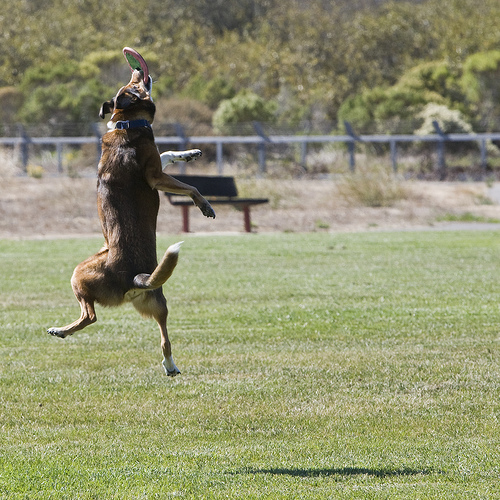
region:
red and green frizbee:
[108, 45, 166, 94]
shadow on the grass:
[193, 430, 449, 494]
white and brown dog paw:
[147, 340, 195, 392]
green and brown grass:
[251, 281, 426, 458]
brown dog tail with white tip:
[108, 232, 198, 300]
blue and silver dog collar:
[61, 106, 172, 147]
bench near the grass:
[162, 165, 272, 250]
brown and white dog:
[50, 69, 187, 416]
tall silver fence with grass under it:
[234, 113, 490, 185]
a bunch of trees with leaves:
[182, 22, 464, 119]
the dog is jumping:
[89, 37, 255, 259]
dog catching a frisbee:
[42, 26, 225, 386]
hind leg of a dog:
[28, 258, 129, 357]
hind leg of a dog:
[141, 288, 185, 395]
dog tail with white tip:
[131, 233, 191, 305]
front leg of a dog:
[118, 153, 233, 220]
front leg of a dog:
[141, 140, 211, 182]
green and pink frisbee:
[112, 34, 160, 92]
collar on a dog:
[102, 111, 159, 143]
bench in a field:
[145, 163, 261, 241]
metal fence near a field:
[0, 107, 495, 194]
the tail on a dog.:
[127, 235, 199, 302]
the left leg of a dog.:
[45, 246, 112, 347]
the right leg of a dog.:
[126, 271, 178, 378]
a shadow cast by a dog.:
[230, 444, 447, 498]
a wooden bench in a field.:
[149, 163, 296, 235]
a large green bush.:
[398, 93, 485, 159]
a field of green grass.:
[0, 225, 494, 498]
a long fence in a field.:
[0, 123, 496, 187]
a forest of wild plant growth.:
[0, 0, 497, 175]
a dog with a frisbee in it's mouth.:
[38, 19, 187, 382]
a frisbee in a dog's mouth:
[115, 40, 156, 87]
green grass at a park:
[1, 220, 493, 496]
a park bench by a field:
[150, 160, 285, 232]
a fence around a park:
[7, 117, 493, 172]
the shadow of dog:
[231, 450, 446, 490]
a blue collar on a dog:
[101, 106, 157, 132]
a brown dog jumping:
[55, 47, 191, 369]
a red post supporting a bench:
[180, 201, 196, 228]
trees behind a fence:
[2, 1, 496, 130]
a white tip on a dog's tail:
[164, 234, 186, 254]